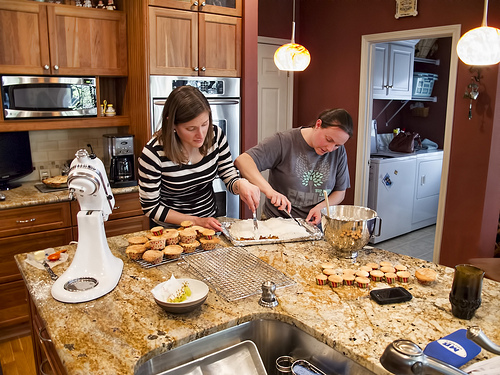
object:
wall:
[281, 0, 359, 153]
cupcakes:
[415, 267, 436, 284]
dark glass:
[449, 263, 486, 320]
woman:
[138, 83, 261, 230]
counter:
[13, 214, 499, 374]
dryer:
[417, 144, 443, 229]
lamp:
[269, 0, 312, 77]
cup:
[448, 262, 487, 322]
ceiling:
[0, 0, 500, 24]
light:
[456, 0, 500, 67]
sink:
[129, 313, 388, 375]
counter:
[2, 161, 143, 215]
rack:
[180, 245, 298, 302]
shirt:
[239, 125, 352, 223]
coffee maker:
[102, 132, 139, 187]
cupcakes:
[397, 270, 412, 282]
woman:
[234, 109, 361, 223]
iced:
[235, 221, 249, 233]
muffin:
[148, 238, 167, 249]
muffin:
[180, 231, 197, 243]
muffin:
[326, 275, 344, 287]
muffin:
[199, 238, 218, 250]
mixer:
[47, 145, 124, 302]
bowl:
[320, 205, 383, 261]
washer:
[366, 144, 414, 245]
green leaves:
[302, 168, 323, 188]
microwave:
[1, 74, 96, 119]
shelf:
[0, 74, 127, 132]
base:
[43, 251, 122, 305]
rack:
[122, 237, 224, 277]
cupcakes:
[125, 244, 146, 260]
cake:
[228, 216, 309, 243]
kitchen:
[0, 3, 497, 375]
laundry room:
[356, 26, 458, 258]